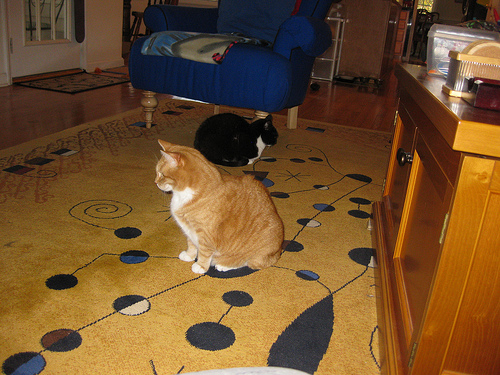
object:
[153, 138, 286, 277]
cat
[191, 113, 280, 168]
cat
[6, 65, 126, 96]
mat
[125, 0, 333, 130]
chair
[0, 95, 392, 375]
carpet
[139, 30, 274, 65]
blanket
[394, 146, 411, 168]
knobs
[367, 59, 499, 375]
cabinet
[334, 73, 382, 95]
feed and water bowls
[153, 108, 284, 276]
cats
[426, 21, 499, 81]
container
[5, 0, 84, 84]
door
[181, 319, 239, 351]
tound design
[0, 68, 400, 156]
floor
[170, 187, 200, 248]
fur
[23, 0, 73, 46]
window panels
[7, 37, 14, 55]
hinge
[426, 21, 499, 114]
items